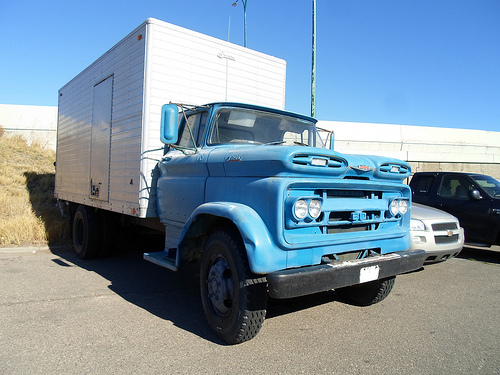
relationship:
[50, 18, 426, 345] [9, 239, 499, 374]
truck parked in parking lot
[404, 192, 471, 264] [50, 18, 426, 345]
car parked next to truck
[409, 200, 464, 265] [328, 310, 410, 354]
car parked in lot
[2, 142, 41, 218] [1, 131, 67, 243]
patch of grass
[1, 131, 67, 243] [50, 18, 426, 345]
grass behind truck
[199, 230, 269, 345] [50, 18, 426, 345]
tire on truck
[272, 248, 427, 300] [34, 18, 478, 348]
bumpers on truck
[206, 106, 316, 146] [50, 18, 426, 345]
windshield on truck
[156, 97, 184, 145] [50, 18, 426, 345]
mirror on truck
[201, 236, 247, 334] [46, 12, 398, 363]
tire on truck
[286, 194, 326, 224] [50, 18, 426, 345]
headlight of truck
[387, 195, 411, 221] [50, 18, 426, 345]
headlight of truck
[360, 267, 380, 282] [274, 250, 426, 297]
license plate on bumper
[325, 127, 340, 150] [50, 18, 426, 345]
mirror on truck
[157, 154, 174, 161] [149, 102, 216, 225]
handle on door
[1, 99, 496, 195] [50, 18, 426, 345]
wall behind truck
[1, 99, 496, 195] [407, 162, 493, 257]
wall behind truck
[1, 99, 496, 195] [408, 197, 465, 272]
wall behind car